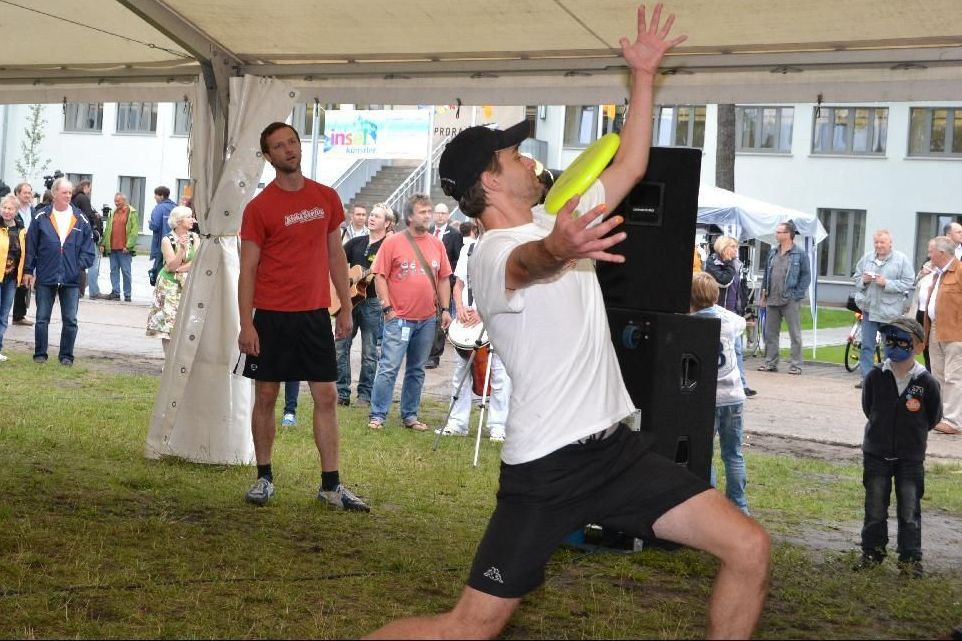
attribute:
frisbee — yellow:
[525, 135, 617, 218]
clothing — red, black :
[232, 172, 361, 387]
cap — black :
[452, 103, 541, 195]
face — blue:
[877, 323, 926, 360]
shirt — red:
[369, 231, 444, 320]